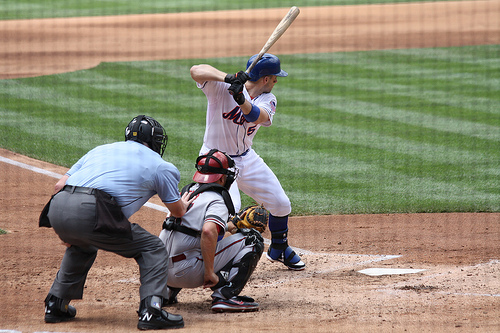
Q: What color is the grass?
A: Green.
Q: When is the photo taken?
A: Day time.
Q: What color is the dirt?
A: Brown.